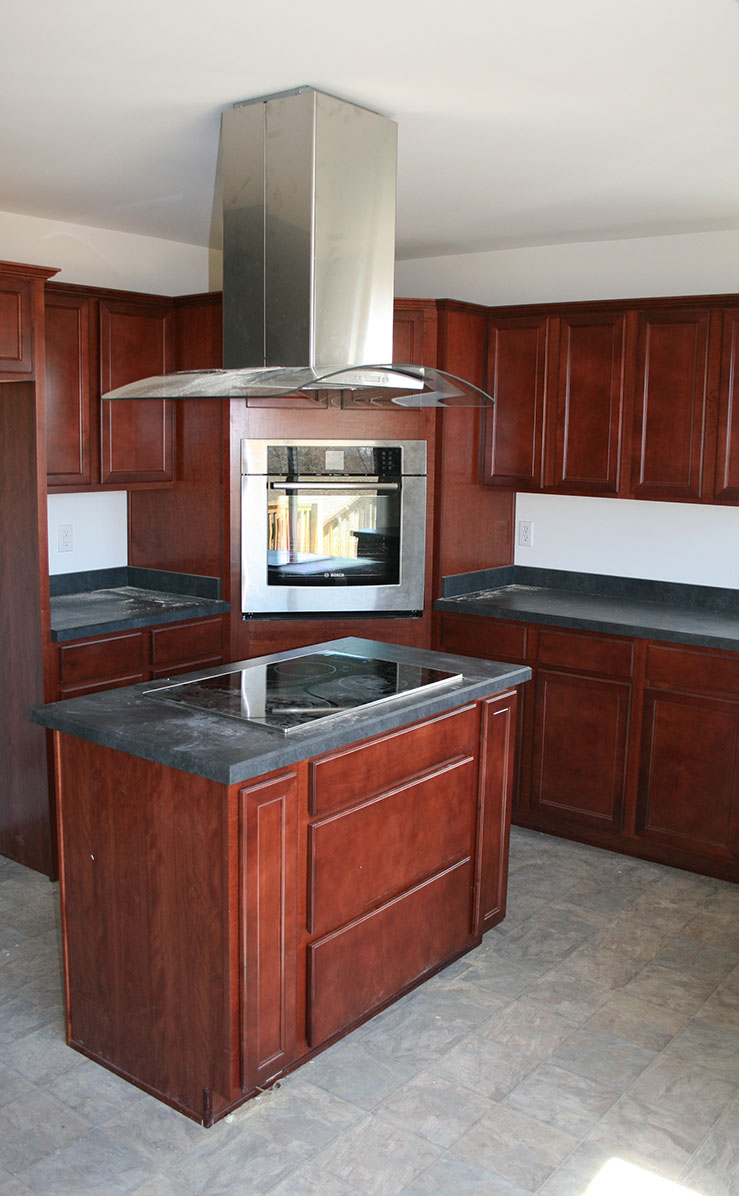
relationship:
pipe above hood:
[226, 93, 398, 364] [104, 360, 492, 409]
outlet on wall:
[51, 513, 81, 558] [47, 490, 136, 583]